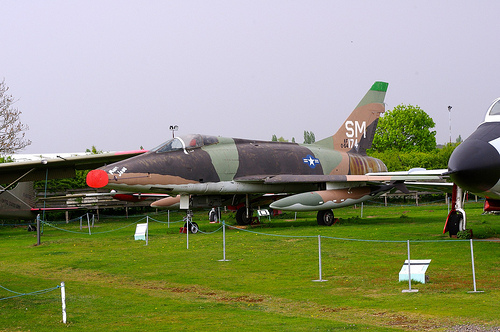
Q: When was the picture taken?
A: Daytime.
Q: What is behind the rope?
A: Airplanes.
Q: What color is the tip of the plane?
A: Red.